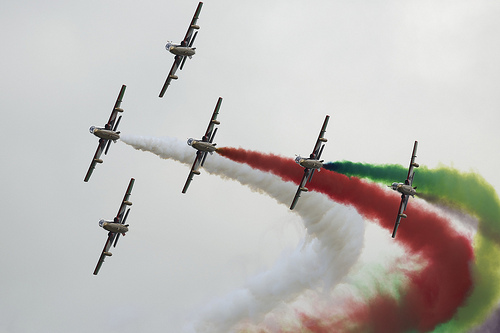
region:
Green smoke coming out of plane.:
[342, 145, 499, 211]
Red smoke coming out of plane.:
[241, 133, 388, 215]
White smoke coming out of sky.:
[138, 125, 304, 215]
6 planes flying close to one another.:
[66, 28, 430, 244]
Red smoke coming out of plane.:
[229, 145, 350, 198]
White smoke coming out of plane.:
[153, 135, 263, 222]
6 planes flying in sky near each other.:
[61, 11, 427, 286]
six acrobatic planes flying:
[78, 18, 443, 267]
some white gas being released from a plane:
[296, 213, 356, 273]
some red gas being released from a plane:
[410, 229, 466, 308]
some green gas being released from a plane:
[435, 171, 492, 201]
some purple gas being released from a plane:
[483, 297, 498, 327]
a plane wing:
[112, 170, 145, 215]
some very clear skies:
[265, 16, 457, 78]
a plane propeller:
[95, 214, 108, 233]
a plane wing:
[177, 4, 207, 42]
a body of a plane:
[172, 41, 199, 61]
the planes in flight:
[66, 21, 417, 291]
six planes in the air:
[75, 41, 446, 271]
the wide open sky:
[22, 10, 453, 308]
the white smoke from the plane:
[124, 127, 320, 312]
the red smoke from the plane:
[223, 138, 432, 331]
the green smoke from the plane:
[329, 141, 499, 296]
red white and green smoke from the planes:
[148, 116, 485, 318]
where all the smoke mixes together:
[264, 270, 486, 324]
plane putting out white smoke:
[89, 113, 157, 162]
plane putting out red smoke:
[176, 101, 246, 180]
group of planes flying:
[60, 1, 454, 306]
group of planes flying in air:
[62, 0, 440, 294]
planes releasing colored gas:
[72, 0, 450, 288]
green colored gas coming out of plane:
[292, 119, 449, 216]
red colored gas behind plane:
[174, 91, 292, 191]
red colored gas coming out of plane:
[181, 85, 288, 199]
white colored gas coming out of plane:
[70, 79, 165, 196]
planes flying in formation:
[37, 1, 452, 283]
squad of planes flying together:
[57, 3, 464, 273]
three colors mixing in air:
[204, 126, 395, 207]